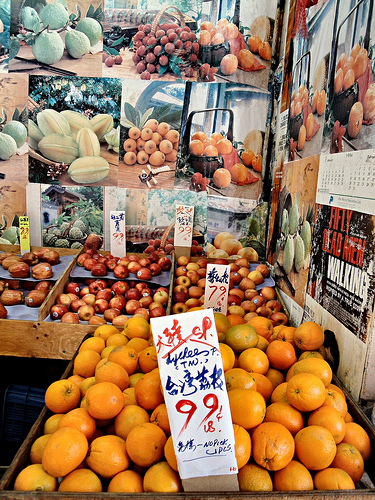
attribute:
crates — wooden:
[5, 236, 373, 496]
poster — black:
[312, 203, 374, 330]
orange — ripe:
[286, 372, 326, 412]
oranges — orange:
[257, 363, 329, 451]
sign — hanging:
[305, 202, 374, 343]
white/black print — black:
[313, 149, 374, 205]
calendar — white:
[317, 13, 373, 214]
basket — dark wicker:
[184, 104, 237, 180]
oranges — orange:
[18, 308, 371, 491]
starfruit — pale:
[42, 108, 60, 150]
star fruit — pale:
[28, 110, 119, 183]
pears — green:
[24, 21, 99, 59]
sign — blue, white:
[201, 261, 231, 315]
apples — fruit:
[124, 288, 138, 300]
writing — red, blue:
[155, 316, 236, 475]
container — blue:
[4, 376, 57, 446]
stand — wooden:
[0, 243, 373, 497]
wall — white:
[310, 5, 349, 55]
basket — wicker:
[133, 5, 194, 73]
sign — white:
[148, 306, 238, 479]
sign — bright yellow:
[15, 217, 34, 257]